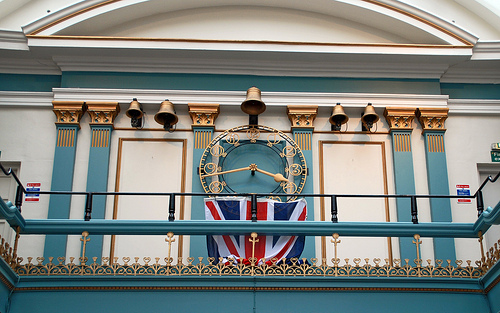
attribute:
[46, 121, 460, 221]
wall — blue, white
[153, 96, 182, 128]
bell — copper 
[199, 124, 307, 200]
clock — gold, large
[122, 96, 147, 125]
bell — brass, large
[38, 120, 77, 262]
pillar — baby blue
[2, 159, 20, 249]
doorway — white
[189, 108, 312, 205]
clock — metal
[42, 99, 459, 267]
decorative pillars — blue, gold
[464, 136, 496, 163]
sign — green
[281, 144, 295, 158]
2 — gold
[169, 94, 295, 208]
number — colored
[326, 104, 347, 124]
bell — large, brass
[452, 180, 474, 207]
sign — red, white, blue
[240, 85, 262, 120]
bell — brass, large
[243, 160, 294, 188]
hour hand — gold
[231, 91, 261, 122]
bell — gold, colored, metal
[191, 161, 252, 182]
hand — gold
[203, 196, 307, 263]
flag — United Kingdom flag, white, blue, red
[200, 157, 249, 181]
hand — large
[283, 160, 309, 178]
number 3 — gold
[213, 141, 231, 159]
9 — number 9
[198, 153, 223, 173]
metal-work — gold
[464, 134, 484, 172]
lettering — white